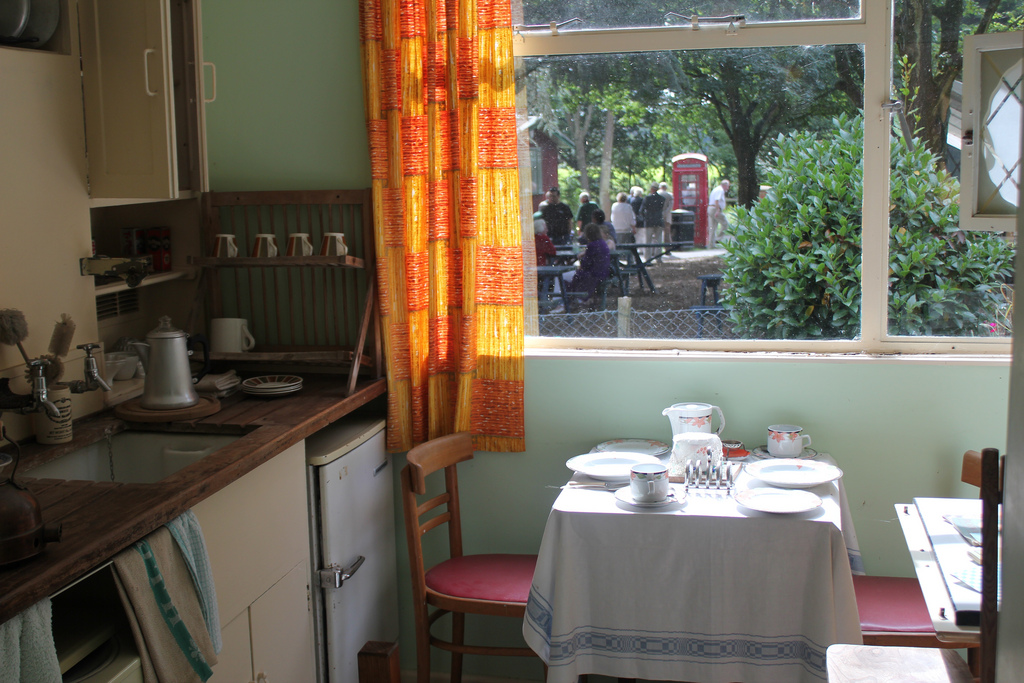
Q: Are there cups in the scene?
A: Yes, there is a cup.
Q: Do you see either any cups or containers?
A: Yes, there is a cup.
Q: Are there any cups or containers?
A: Yes, there is a cup.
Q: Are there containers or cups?
A: Yes, there is a cup.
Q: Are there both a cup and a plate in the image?
A: Yes, there are both a cup and a plate.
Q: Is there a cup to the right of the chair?
A: Yes, there is a cup to the right of the chair.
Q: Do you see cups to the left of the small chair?
A: No, the cup is to the right of the chair.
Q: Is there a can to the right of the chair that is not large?
A: No, there is a cup to the right of the chair.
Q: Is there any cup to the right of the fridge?
A: Yes, there is a cup to the right of the fridge.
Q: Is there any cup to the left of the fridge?
A: No, the cup is to the right of the fridge.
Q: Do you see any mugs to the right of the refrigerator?
A: No, there is a cup to the right of the refrigerator.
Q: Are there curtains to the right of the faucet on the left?
A: Yes, there is a curtain to the right of the faucet.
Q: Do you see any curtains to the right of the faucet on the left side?
A: Yes, there is a curtain to the right of the faucet.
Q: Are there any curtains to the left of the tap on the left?
A: No, the curtain is to the right of the tap.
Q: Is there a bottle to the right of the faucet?
A: No, there is a curtain to the right of the faucet.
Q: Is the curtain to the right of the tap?
A: Yes, the curtain is to the right of the tap.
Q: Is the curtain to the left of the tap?
A: No, the curtain is to the right of the tap.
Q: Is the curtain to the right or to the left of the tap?
A: The curtain is to the right of the tap.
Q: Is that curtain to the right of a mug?
A: No, the curtain is to the right of a cup.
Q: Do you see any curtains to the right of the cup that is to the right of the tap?
A: Yes, there is a curtain to the right of the cup.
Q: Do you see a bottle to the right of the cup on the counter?
A: No, there is a curtain to the right of the cup.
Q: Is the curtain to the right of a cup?
A: Yes, the curtain is to the right of a cup.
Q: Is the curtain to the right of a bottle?
A: No, the curtain is to the right of a cup.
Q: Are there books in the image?
A: No, there are no books.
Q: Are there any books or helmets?
A: No, there are no books or helmets.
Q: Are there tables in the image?
A: Yes, there is a table.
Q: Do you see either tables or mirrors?
A: Yes, there is a table.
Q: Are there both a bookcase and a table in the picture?
A: No, there is a table but no bookcases.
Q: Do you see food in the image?
A: No, there is no food.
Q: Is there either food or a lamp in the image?
A: No, there are no food or lamps.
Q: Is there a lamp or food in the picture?
A: No, there are no food or lamps.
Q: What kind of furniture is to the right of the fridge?
A: The piece of furniture is a table.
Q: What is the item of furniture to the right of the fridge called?
A: The piece of furniture is a table.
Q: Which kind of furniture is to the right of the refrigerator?
A: The piece of furniture is a table.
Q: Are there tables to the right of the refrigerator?
A: Yes, there is a table to the right of the refrigerator.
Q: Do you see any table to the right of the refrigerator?
A: Yes, there is a table to the right of the refrigerator.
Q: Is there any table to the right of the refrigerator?
A: Yes, there is a table to the right of the refrigerator.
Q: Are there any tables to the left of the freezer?
A: No, the table is to the right of the freezer.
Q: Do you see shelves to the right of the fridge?
A: No, there is a table to the right of the fridge.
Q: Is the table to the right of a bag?
A: No, the table is to the right of a refrigerator.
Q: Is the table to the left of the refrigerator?
A: No, the table is to the right of the refrigerator.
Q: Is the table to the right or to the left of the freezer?
A: The table is to the right of the freezer.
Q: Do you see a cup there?
A: Yes, there is a cup.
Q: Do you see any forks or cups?
A: Yes, there is a cup.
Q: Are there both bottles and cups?
A: No, there is a cup but no bottles.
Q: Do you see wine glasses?
A: No, there are no wine glasses.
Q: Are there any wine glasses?
A: No, there are no wine glasses.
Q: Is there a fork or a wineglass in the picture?
A: No, there are no wine glasses or forks.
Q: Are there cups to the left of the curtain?
A: Yes, there is a cup to the left of the curtain.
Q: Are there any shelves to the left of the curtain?
A: No, there is a cup to the left of the curtain.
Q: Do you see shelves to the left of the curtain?
A: No, there is a cup to the left of the curtain.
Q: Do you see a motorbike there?
A: No, there are no motorcycles.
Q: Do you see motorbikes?
A: No, there are no motorbikes.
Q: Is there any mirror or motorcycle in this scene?
A: No, there are no motorcycles or mirrors.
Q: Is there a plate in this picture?
A: Yes, there is a plate.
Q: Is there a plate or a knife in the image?
A: Yes, there is a plate.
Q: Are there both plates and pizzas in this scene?
A: No, there is a plate but no pizzas.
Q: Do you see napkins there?
A: No, there are no napkins.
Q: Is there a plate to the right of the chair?
A: Yes, there is a plate to the right of the chair.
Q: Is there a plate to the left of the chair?
A: No, the plate is to the right of the chair.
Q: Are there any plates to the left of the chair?
A: No, the plate is to the right of the chair.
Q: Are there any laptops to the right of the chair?
A: No, there is a plate to the right of the chair.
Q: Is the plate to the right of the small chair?
A: Yes, the plate is to the right of the chair.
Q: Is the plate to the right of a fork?
A: No, the plate is to the right of the chair.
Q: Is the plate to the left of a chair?
A: No, the plate is to the right of a chair.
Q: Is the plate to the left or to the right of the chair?
A: The plate is to the right of the chair.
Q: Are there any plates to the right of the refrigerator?
A: Yes, there is a plate to the right of the refrigerator.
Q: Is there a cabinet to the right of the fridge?
A: No, there is a plate to the right of the fridge.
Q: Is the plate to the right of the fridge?
A: Yes, the plate is to the right of the fridge.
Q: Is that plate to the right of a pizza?
A: No, the plate is to the right of the fridge.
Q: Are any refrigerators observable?
A: Yes, there is a refrigerator.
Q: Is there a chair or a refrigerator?
A: Yes, there is a refrigerator.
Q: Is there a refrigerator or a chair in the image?
A: Yes, there is a refrigerator.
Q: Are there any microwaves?
A: No, there are no microwaves.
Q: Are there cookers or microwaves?
A: No, there are no microwaves or cookers.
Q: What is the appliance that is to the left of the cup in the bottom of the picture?
A: The appliance is a refrigerator.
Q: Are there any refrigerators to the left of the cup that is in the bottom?
A: Yes, there is a refrigerator to the left of the cup.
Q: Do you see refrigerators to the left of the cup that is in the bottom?
A: Yes, there is a refrigerator to the left of the cup.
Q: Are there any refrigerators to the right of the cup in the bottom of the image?
A: No, the refrigerator is to the left of the cup.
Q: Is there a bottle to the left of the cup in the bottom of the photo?
A: No, there is a refrigerator to the left of the cup.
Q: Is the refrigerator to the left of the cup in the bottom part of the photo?
A: Yes, the refrigerator is to the left of the cup.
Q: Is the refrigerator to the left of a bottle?
A: No, the refrigerator is to the left of the cup.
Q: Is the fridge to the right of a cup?
A: No, the fridge is to the left of a cup.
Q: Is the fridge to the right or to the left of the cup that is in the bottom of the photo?
A: The fridge is to the left of the cup.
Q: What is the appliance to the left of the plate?
A: The appliance is a refrigerator.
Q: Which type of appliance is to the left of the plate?
A: The appliance is a refrigerator.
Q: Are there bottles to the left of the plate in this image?
A: No, there is a refrigerator to the left of the plate.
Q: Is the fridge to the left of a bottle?
A: No, the fridge is to the left of the plate.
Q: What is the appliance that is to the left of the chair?
A: The appliance is a refrigerator.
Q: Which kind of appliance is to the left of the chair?
A: The appliance is a refrigerator.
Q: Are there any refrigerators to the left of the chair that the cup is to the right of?
A: Yes, there is a refrigerator to the left of the chair.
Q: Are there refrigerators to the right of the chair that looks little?
A: No, the refrigerator is to the left of the chair.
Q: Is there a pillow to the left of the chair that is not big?
A: No, there is a refrigerator to the left of the chair.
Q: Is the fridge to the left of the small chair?
A: Yes, the fridge is to the left of the chair.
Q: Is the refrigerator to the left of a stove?
A: No, the refrigerator is to the left of the chair.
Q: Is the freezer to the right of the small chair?
A: No, the freezer is to the left of the chair.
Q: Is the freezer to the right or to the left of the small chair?
A: The freezer is to the left of the chair.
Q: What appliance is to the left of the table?
A: The appliance is a refrigerator.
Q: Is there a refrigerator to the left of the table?
A: Yes, there is a refrigerator to the left of the table.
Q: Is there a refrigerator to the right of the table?
A: No, the refrigerator is to the left of the table.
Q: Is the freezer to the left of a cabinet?
A: No, the freezer is to the left of the table.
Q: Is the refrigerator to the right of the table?
A: No, the refrigerator is to the left of the table.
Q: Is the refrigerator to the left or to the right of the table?
A: The refrigerator is to the left of the table.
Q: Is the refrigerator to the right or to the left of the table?
A: The refrigerator is to the left of the table.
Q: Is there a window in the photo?
A: Yes, there is a window.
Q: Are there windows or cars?
A: Yes, there is a window.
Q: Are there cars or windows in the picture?
A: Yes, there is a window.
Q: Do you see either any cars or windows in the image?
A: Yes, there is a window.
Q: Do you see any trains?
A: No, there are no trains.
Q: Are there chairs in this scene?
A: Yes, there is a chair.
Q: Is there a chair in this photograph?
A: Yes, there is a chair.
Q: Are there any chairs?
A: Yes, there is a chair.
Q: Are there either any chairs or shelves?
A: Yes, there is a chair.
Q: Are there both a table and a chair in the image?
A: Yes, there are both a chair and a table.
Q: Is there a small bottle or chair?
A: Yes, there is a small chair.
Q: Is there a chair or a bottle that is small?
A: Yes, the chair is small.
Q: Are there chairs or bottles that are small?
A: Yes, the chair is small.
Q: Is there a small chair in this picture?
A: Yes, there is a small chair.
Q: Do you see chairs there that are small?
A: Yes, there is a small chair.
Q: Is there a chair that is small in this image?
A: Yes, there is a small chair.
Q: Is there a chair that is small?
A: Yes, there is a chair that is small.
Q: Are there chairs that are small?
A: Yes, there is a chair that is small.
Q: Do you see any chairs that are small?
A: Yes, there is a chair that is small.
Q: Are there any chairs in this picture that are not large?
A: Yes, there is a small chair.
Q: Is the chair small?
A: Yes, the chair is small.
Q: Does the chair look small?
A: Yes, the chair is small.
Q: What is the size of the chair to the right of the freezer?
A: The chair is small.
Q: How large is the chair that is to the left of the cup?
A: The chair is small.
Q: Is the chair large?
A: No, the chair is small.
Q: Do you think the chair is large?
A: No, the chair is small.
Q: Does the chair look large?
A: No, the chair is small.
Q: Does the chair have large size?
A: No, the chair is small.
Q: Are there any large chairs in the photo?
A: No, there is a chair but it is small.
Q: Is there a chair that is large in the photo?
A: No, there is a chair but it is small.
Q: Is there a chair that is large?
A: No, there is a chair but it is small.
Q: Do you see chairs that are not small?
A: No, there is a chair but it is small.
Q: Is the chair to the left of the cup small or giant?
A: The chair is small.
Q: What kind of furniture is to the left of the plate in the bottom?
A: The piece of furniture is a chair.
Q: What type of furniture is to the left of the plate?
A: The piece of furniture is a chair.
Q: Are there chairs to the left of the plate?
A: Yes, there is a chair to the left of the plate.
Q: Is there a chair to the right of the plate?
A: No, the chair is to the left of the plate.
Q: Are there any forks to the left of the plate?
A: No, there is a chair to the left of the plate.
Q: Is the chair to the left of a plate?
A: Yes, the chair is to the left of a plate.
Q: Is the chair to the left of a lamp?
A: No, the chair is to the left of a plate.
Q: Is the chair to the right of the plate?
A: No, the chair is to the left of the plate.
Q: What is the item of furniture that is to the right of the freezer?
A: The piece of furniture is a chair.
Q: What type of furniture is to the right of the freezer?
A: The piece of furniture is a chair.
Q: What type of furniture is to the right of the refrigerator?
A: The piece of furniture is a chair.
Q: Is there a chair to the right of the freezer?
A: Yes, there is a chair to the right of the freezer.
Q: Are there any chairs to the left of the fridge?
A: No, the chair is to the right of the fridge.